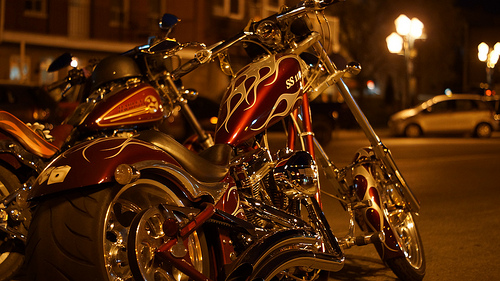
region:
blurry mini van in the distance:
[383, 85, 498, 141]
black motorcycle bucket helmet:
[74, 49, 157, 91]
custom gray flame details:
[216, 47, 309, 147]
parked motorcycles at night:
[1, 2, 451, 279]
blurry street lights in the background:
[383, 10, 425, 100]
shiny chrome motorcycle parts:
[232, 150, 342, 277]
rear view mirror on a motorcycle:
[41, 46, 82, 74]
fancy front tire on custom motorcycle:
[337, 141, 439, 278]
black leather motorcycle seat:
[128, 125, 243, 181]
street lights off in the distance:
[475, 37, 498, 85]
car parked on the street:
[386, 88, 498, 140]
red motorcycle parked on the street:
[50, 13, 426, 280]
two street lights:
[380, 6, 496, 106]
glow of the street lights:
[382, 13, 498, 70]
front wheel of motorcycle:
[355, 164, 430, 271]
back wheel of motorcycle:
[45, 155, 214, 279]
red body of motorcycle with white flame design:
[34, 43, 327, 249]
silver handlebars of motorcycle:
[173, 0, 333, 91]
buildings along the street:
[2, 8, 351, 128]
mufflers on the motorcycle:
[220, 189, 353, 279]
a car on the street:
[390, 93, 498, 143]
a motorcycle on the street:
[53, 5, 432, 280]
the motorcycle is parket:
[22, 2, 434, 279]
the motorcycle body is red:
[44, 54, 297, 197]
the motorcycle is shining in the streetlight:
[32, 23, 417, 278]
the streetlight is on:
[378, 15, 435, 108]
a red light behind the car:
[482, 87, 495, 100]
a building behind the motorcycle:
[10, 1, 377, 118]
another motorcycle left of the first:
[1, 32, 193, 218]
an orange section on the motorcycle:
[0, 112, 65, 158]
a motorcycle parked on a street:
[21, 16, 393, 280]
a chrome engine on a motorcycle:
[222, 139, 327, 230]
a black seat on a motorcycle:
[140, 113, 235, 171]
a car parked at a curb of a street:
[385, 80, 492, 142]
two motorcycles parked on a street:
[2, 19, 434, 274]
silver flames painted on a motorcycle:
[219, 56, 284, 135]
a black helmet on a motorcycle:
[75, 45, 147, 102]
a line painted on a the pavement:
[410, 141, 494, 178]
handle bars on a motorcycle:
[191, 0, 331, 87]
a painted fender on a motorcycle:
[350, 150, 403, 257]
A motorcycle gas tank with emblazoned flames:
[200, 50, 314, 150]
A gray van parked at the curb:
[385, 88, 497, 149]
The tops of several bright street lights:
[379, 13, 434, 68]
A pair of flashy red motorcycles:
[14, 7, 410, 267]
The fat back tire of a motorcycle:
[29, 180, 213, 279]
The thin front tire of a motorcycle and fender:
[343, 141, 430, 276]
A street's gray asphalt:
[423, 155, 494, 276]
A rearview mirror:
[39, 43, 79, 77]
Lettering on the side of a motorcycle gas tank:
[276, 64, 306, 97]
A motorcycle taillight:
[112, 163, 137, 186]